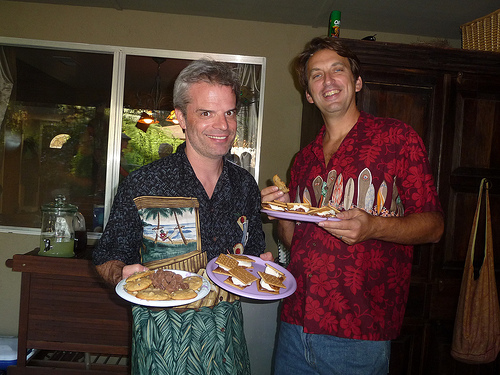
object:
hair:
[287, 36, 357, 96]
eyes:
[198, 112, 213, 118]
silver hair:
[172, 51, 239, 116]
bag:
[446, 176, 498, 366]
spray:
[327, 10, 341, 37]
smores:
[255, 269, 286, 296]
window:
[0, 44, 118, 239]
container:
[37, 194, 80, 259]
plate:
[277, 190, 334, 252]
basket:
[457, 9, 499, 50]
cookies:
[123, 278, 154, 291]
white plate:
[114, 268, 212, 309]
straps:
[482, 180, 493, 262]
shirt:
[89, 143, 268, 268]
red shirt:
[278, 111, 444, 342]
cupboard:
[298, 37, 499, 374]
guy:
[92, 53, 272, 374]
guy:
[260, 36, 446, 374]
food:
[223, 266, 260, 291]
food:
[270, 174, 290, 194]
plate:
[205, 253, 297, 300]